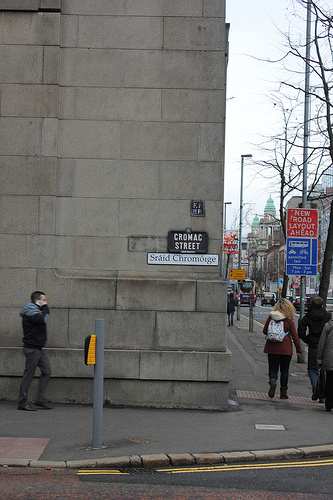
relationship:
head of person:
[29, 288, 48, 313] [14, 272, 66, 419]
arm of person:
[37, 299, 50, 318] [17, 283, 76, 427]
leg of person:
[15, 349, 41, 402] [18, 290, 57, 413]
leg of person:
[38, 359, 51, 395] [19, 287, 55, 410]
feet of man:
[18, 405, 37, 411] [17, 291, 53, 411]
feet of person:
[17, 400, 35, 411] [19, 287, 55, 410]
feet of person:
[31, 394, 55, 413] [19, 287, 55, 410]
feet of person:
[264, 377, 277, 400] [265, 296, 304, 399]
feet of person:
[278, 383, 289, 397] [265, 296, 304, 399]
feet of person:
[268, 378, 277, 397] [261, 296, 303, 398]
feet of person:
[280, 386, 289, 399] [261, 296, 303, 398]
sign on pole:
[228, 267, 247, 281] [235, 152, 252, 321]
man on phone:
[17, 291, 53, 411] [32, 298, 41, 308]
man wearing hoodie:
[17, 291, 53, 411] [19, 302, 50, 349]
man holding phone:
[17, 291, 53, 411] [33, 299, 42, 307]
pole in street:
[88, 324, 134, 404] [6, 436, 332, 494]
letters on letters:
[289, 209, 315, 239] [289, 209, 314, 237]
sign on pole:
[279, 239, 324, 277] [296, 2, 315, 368]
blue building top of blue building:
[260, 191, 276, 215] [248, 206, 260, 231]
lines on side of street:
[75, 457, 331, 473] [6, 436, 332, 494]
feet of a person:
[18, 405, 37, 411] [19, 288, 42, 397]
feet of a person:
[268, 378, 277, 397] [257, 300, 296, 377]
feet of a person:
[315, 390, 327, 399] [303, 295, 325, 340]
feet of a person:
[225, 317, 241, 329] [226, 292, 236, 312]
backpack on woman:
[267, 317, 290, 342] [263, 299, 302, 398]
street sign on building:
[164, 227, 207, 255] [5, 7, 247, 416]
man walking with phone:
[17, 291, 53, 411] [32, 295, 41, 309]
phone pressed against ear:
[32, 295, 41, 309] [33, 296, 37, 306]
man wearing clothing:
[16, 283, 69, 424] [18, 298, 61, 413]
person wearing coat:
[262, 297, 302, 399] [261, 308, 308, 362]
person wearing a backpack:
[262, 297, 302, 399] [265, 314, 287, 344]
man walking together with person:
[297, 295, 332, 400] [262, 297, 302, 399]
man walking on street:
[297, 295, 332, 400] [0, 299, 332, 497]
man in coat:
[297, 295, 332, 400] [297, 307, 330, 348]